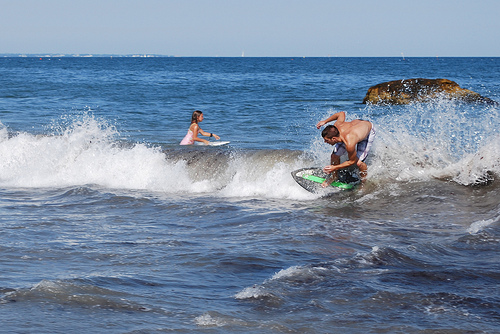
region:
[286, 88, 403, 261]
PErson in the water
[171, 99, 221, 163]
PErson in the water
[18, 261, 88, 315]
ripples in the water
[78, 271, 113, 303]
ripples in the water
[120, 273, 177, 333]
ripples in the water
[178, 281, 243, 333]
ripples in the water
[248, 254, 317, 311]
ripples in the water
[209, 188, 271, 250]
ripples in the water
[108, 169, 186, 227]
ripples in the water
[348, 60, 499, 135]
Large rock in the water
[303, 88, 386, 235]
a male surfing in the ocean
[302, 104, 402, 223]
a man falling off his surf board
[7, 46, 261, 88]
the coastline in the distance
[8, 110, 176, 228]
the white caps on the waves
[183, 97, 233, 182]
a girl with a white bathing suit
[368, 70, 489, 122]
a rock jutting out of the water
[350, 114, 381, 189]
man with plaid swim trunks on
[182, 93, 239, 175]
girl getting ready to get on her surf board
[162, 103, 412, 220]
two people surfing in the ocean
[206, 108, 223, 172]
a black watch on wrist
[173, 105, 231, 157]
girl in white bathing suit with white surfboard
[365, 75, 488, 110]
large brown rock in ocean water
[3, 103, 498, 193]
white crest of wave in ocean water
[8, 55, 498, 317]
bright blue ocean water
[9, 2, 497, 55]
clear blue sunny cloudless sky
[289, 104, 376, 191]
shirtless man leaning over while surfing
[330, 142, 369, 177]
white shorts on surfing man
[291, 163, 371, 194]
black surfboard with lime green stripe down middle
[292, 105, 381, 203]
dark haired young man surfing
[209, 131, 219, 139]
black wriast band on young blond girl preparing to surf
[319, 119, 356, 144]
the head of a man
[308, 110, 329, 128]
the hand of a man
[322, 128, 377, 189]
the arm of a man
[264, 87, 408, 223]
a man on a surfboard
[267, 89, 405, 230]
a man surfing in the ocean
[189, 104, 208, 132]
the head of a woman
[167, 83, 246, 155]
a woman in the ocean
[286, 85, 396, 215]
a man in the ocean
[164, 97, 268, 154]
a woman on a surfboard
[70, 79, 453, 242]
people surfing in the water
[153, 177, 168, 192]
wave in the ocean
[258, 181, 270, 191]
wave in the ocean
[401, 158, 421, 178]
wave in the ocean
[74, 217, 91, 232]
wave in the ocean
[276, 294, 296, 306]
wave in the ocean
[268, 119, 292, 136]
wave in the ocean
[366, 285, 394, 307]
wave in the ocean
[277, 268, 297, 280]
wave in the ocean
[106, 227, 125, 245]
wave in the ocean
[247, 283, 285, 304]
wave in the ocean